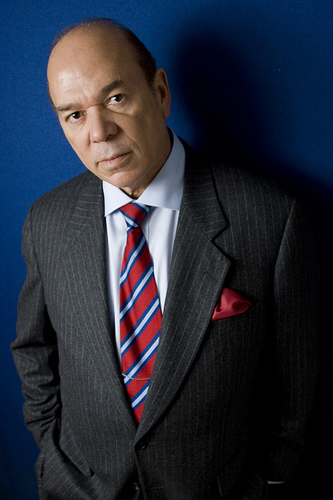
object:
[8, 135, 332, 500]
suit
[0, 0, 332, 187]
background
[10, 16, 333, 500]
person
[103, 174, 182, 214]
collar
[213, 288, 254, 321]
object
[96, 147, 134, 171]
mouth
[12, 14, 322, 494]
man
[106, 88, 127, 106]
eye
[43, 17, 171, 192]
head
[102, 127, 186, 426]
shirt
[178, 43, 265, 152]
shadow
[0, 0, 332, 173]
wall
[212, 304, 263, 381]
pocket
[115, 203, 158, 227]
knot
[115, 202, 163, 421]
tie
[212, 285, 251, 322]
handkerchief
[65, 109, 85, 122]
eye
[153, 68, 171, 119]
ear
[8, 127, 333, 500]
jacket